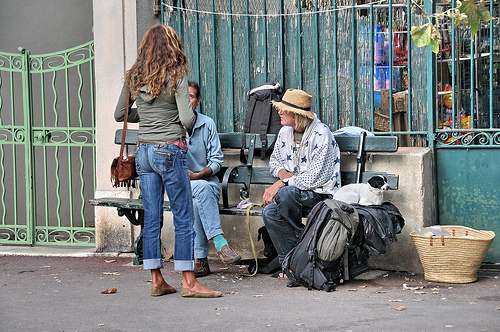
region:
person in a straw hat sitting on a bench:
[261, 82, 347, 287]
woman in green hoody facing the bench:
[110, 16, 228, 300]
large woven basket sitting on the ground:
[407, 218, 495, 283]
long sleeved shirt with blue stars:
[265, 116, 346, 195]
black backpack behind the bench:
[239, 77, 287, 157]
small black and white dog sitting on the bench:
[331, 171, 393, 208]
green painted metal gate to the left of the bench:
[1, 38, 101, 253]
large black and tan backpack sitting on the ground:
[283, 196, 363, 293]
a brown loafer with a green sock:
[209, 231, 241, 266]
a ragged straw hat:
[271, 85, 323, 124]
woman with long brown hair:
[96, 13, 231, 307]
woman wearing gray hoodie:
[106, 11, 212, 311]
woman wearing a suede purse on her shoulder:
[78, 26, 219, 318]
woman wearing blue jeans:
[105, 25, 225, 329]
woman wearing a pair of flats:
[103, 33, 228, 315]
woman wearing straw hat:
[236, 50, 395, 298]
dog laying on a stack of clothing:
[285, 163, 420, 297]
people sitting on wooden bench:
[67, 106, 474, 276]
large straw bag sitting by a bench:
[388, 218, 498, 300]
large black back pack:
[211, 73, 293, 185]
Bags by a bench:
[295, 180, 435, 285]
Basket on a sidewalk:
[401, 210, 492, 294]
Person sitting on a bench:
[249, 93, 349, 285]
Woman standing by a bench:
[104, 16, 224, 293]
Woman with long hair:
[113, 24, 208, 204]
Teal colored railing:
[143, 15, 499, 130]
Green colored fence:
[3, 45, 120, 263]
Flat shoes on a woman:
[140, 273, 250, 311]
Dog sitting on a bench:
[323, 163, 388, 218]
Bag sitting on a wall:
[237, 80, 298, 155]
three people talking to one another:
[92, 21, 436, 305]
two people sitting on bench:
[90, 22, 360, 260]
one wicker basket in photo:
[391, 211, 496, 296]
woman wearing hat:
[272, 71, 336, 129]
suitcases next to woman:
[235, 77, 376, 308]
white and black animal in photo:
[325, 161, 412, 222]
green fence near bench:
[1, 10, 179, 322]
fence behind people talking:
[150, 1, 485, 136]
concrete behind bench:
[100, 112, 497, 280]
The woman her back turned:
[109, 21, 225, 298]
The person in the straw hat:
[260, 85, 345, 278]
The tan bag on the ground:
[410, 221, 495, 284]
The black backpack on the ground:
[279, 196, 361, 295]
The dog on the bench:
[331, 168, 388, 207]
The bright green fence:
[0, 35, 98, 249]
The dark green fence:
[156, 0, 499, 163]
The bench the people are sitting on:
[87, 121, 400, 281]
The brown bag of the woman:
[106, 75, 136, 192]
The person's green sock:
[212, 231, 228, 251]